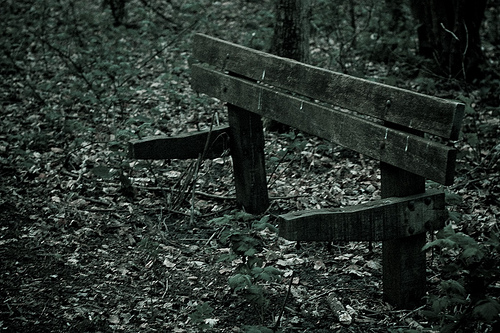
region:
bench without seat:
[165, 23, 469, 264]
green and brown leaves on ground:
[21, 202, 76, 244]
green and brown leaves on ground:
[190, 269, 227, 299]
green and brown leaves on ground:
[138, 261, 195, 299]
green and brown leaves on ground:
[41, 276, 105, 328]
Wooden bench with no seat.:
[119, 24, 469, 314]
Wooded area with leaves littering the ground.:
[2, 3, 499, 332]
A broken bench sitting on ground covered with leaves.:
[5, 4, 498, 330]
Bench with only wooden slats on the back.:
[120, 27, 465, 309]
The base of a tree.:
[259, 3, 319, 69]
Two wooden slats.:
[188, 30, 466, 190]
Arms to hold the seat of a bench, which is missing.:
[124, 128, 453, 243]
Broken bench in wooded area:
[114, 22, 466, 308]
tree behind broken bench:
[256, 3, 323, 68]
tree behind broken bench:
[407, 0, 498, 91]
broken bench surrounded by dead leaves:
[122, 22, 464, 314]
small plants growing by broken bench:
[424, 209, 496, 322]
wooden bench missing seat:
[124, 23, 461, 316]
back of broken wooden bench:
[181, 23, 465, 180]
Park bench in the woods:
[118, 32, 469, 257]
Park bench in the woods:
[116, 20, 466, 320]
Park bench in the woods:
[122, 19, 467, 310]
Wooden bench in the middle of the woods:
[117, 15, 466, 307]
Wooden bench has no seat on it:
[123, 127, 423, 309]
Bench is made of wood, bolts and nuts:
[62, 25, 467, 315]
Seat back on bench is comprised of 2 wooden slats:
[162, 16, 473, 191]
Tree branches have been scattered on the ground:
[37, 90, 369, 301]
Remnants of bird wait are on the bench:
[235, 65, 425, 180]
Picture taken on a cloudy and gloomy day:
[10, 10, 490, 320]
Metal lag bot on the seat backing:
[370, 92, 405, 112]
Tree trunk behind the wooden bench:
[259, 6, 343, 146]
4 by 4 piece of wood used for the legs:
[201, 53, 296, 222]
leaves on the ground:
[123, 270, 166, 320]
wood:
[306, 211, 355, 231]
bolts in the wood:
[381, 94, 395, 106]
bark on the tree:
[278, 20, 307, 50]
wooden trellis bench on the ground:
[189, 35, 445, 170]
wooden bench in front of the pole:
[276, 199, 447, 240]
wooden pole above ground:
[227, 113, 278, 219]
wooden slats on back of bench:
[178, 21, 470, 200]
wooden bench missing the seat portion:
[116, 23, 476, 327]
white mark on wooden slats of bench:
[256, 65, 273, 85]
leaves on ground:
[150, 229, 245, 291]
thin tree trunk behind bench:
[264, 0, 314, 67]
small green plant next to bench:
[411, 216, 499, 331]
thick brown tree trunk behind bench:
[403, 0, 494, 79]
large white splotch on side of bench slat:
[401, 194, 448, 239]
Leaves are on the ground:
[67, 158, 274, 322]